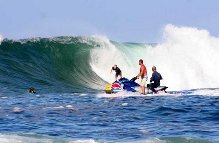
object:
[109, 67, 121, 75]
wet suit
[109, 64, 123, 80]
man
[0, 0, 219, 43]
sky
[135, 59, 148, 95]
man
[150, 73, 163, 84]
shirt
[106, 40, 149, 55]
color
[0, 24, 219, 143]
waters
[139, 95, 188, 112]
wave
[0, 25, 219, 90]
waves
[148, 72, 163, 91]
suit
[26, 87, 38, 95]
person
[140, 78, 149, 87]
shorts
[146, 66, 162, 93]
man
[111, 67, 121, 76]
shirt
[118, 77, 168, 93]
jet ski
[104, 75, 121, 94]
jet ski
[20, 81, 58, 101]
object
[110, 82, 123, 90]
logo